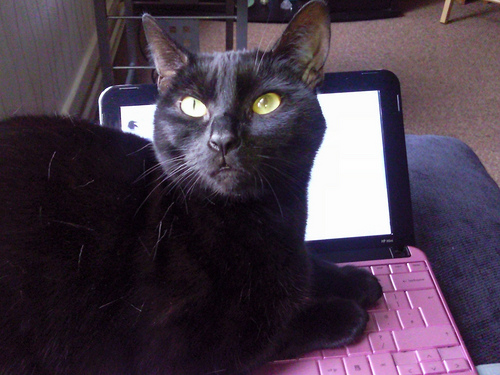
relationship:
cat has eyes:
[9, 1, 415, 369] [172, 90, 292, 126]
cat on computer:
[9, 1, 415, 369] [90, 75, 472, 372]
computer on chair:
[90, 75, 472, 372] [215, 118, 499, 372]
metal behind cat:
[90, 1, 271, 76] [9, 1, 415, 369]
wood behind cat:
[436, 0, 499, 42] [9, 1, 415, 369]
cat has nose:
[9, 1, 415, 369] [203, 121, 244, 153]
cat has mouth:
[9, 1, 415, 369] [207, 158, 245, 180]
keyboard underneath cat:
[215, 260, 477, 375] [9, 1, 415, 369]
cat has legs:
[9, 1, 415, 369] [276, 248, 387, 355]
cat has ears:
[9, 1, 415, 369] [125, 3, 343, 92]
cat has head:
[9, 1, 415, 369] [119, 4, 351, 204]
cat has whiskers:
[9, 1, 415, 369] [145, 157, 307, 212]